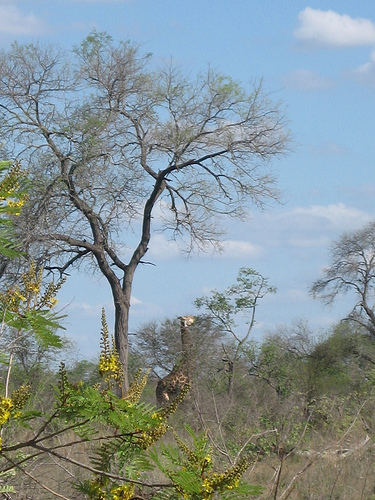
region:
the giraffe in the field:
[147, 299, 200, 433]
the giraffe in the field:
[164, 302, 229, 434]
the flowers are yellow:
[90, 341, 122, 379]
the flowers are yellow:
[192, 450, 247, 498]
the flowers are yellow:
[17, 246, 62, 321]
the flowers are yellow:
[88, 300, 124, 399]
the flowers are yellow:
[165, 405, 246, 496]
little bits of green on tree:
[70, 22, 112, 60]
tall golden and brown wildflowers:
[95, 305, 125, 395]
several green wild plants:
[48, 360, 264, 498]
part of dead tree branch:
[3, 391, 184, 497]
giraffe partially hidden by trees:
[152, 311, 198, 409]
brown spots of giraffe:
[155, 368, 193, 393]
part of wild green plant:
[0, 292, 68, 352]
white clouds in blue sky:
[104, 198, 374, 277]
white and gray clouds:
[276, 5, 374, 86]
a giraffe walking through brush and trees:
[155, 314, 202, 434]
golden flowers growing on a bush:
[95, 309, 127, 394]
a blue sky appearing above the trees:
[1, 0, 371, 361]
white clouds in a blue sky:
[283, 10, 374, 100]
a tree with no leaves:
[4, 27, 303, 401]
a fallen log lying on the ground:
[241, 435, 370, 461]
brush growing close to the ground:
[0, 322, 366, 448]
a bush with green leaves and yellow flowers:
[0, 159, 266, 497]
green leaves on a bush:
[51, 379, 162, 475]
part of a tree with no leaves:
[308, 219, 374, 341]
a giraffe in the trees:
[153, 313, 200, 416]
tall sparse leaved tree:
[8, 32, 267, 372]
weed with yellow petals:
[92, 308, 127, 390]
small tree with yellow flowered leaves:
[5, 179, 248, 489]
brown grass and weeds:
[181, 391, 363, 491]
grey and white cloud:
[276, 0, 373, 98]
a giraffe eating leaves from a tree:
[150, 299, 260, 413]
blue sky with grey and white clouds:
[102, 145, 358, 293]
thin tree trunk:
[103, 278, 139, 410]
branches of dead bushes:
[268, 412, 354, 481]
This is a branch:
[240, 265, 280, 346]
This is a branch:
[195, 290, 241, 351]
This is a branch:
[0, 223, 95, 269]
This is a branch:
[25, 247, 93, 289]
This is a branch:
[165, 179, 229, 282]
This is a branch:
[196, 162, 272, 224]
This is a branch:
[149, 66, 185, 156]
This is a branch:
[177, 67, 294, 160]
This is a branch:
[4, 46, 62, 159]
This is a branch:
[0, 160, 75, 242]